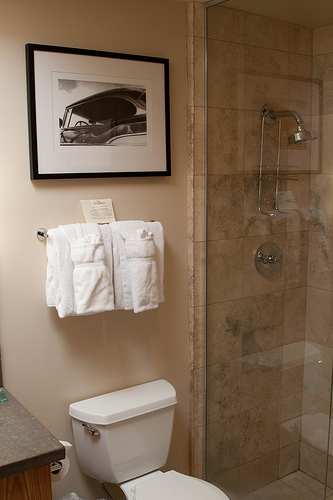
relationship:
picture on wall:
[21, 40, 174, 182] [1, 1, 187, 500]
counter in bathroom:
[0, 381, 66, 477] [0, 0, 332, 500]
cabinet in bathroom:
[0, 464, 53, 499] [0, 0, 332, 500]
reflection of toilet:
[238, 338, 332, 480] [63, 377, 234, 500]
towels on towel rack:
[38, 222, 169, 316] [33, 225, 53, 241]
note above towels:
[75, 194, 117, 230] [38, 222, 169, 316]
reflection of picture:
[228, 67, 326, 181] [21, 40, 174, 182]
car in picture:
[57, 87, 149, 145] [21, 40, 174, 182]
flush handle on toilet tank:
[78, 421, 101, 442] [60, 375, 183, 485]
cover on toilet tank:
[67, 375, 183, 428] [60, 375, 183, 485]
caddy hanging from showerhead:
[253, 110, 292, 223] [261, 105, 318, 150]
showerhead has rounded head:
[261, 105, 318, 150] [291, 130, 321, 143]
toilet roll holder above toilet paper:
[59, 441, 75, 457] [48, 455, 75, 484]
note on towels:
[75, 194, 117, 230] [38, 222, 169, 316]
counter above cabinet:
[0, 381, 66, 477] [0, 464, 53, 499]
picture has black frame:
[21, 40, 174, 182] [21, 40, 44, 186]